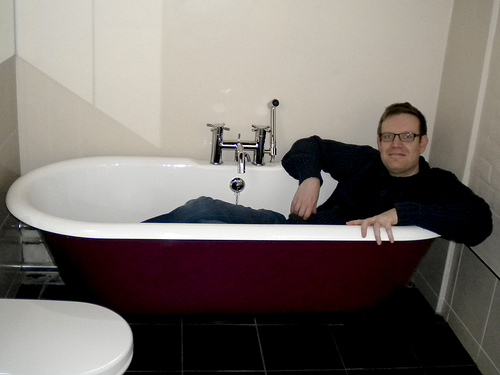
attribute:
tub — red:
[56, 161, 152, 258]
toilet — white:
[19, 293, 111, 349]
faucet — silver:
[205, 129, 270, 178]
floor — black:
[241, 324, 315, 368]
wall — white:
[113, 21, 227, 46]